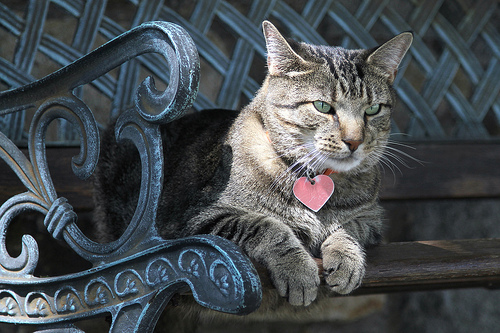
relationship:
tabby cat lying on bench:
[90, 20, 431, 306] [1, 1, 499, 333]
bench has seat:
[1, 1, 499, 333] [1, 140, 499, 296]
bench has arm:
[1, 1, 499, 333] [0, 21, 263, 325]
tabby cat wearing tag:
[90, 20, 431, 306] [292, 173, 336, 212]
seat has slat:
[1, 140, 499, 296] [178, 236, 498, 295]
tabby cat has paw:
[90, 20, 431, 306] [269, 251, 321, 306]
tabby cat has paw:
[90, 20, 431, 306] [320, 234, 366, 294]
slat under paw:
[178, 236, 498, 295] [269, 251, 321, 306]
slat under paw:
[178, 236, 498, 295] [320, 234, 366, 294]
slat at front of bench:
[178, 236, 498, 295] [1, 1, 499, 333]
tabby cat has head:
[90, 20, 431, 306] [261, 21, 413, 172]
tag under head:
[292, 173, 336, 212] [261, 21, 413, 172]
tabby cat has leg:
[90, 20, 431, 306] [155, 156, 321, 307]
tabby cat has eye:
[90, 20, 431, 306] [313, 100, 334, 114]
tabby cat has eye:
[90, 20, 431, 306] [365, 102, 381, 116]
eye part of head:
[313, 100, 334, 114] [261, 21, 413, 172]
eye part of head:
[365, 102, 381, 116] [261, 21, 413, 172]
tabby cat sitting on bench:
[90, 20, 431, 306] [1, 1, 499, 333]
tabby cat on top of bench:
[90, 20, 431, 306] [1, 1, 499, 333]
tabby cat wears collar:
[90, 20, 431, 306] [264, 128, 340, 175]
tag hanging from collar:
[292, 173, 336, 212] [264, 128, 340, 175]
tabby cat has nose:
[90, 20, 431, 306] [340, 115, 366, 152]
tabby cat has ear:
[90, 20, 431, 306] [261, 19, 312, 76]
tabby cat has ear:
[90, 20, 431, 306] [365, 30, 414, 88]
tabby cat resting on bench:
[90, 20, 431, 306] [1, 1, 499, 333]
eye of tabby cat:
[313, 100, 334, 114] [90, 20, 431, 306]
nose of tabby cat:
[340, 115, 366, 152] [90, 20, 431, 306]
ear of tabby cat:
[261, 19, 312, 76] [90, 20, 431, 306]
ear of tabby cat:
[365, 30, 414, 88] [90, 20, 431, 306]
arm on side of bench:
[0, 21, 263, 325] [1, 1, 499, 333]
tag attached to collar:
[292, 173, 336, 212] [264, 128, 340, 175]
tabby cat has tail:
[90, 20, 431, 306] [103, 295, 204, 331]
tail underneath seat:
[103, 295, 204, 331] [1, 140, 499, 296]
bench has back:
[1, 1, 499, 333] [1, 1, 497, 149]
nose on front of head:
[340, 115, 366, 152] [261, 21, 413, 172]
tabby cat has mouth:
[90, 20, 431, 306] [322, 151, 360, 161]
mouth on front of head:
[322, 151, 360, 161] [261, 21, 413, 172]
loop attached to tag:
[305, 166, 318, 183] [292, 173, 336, 212]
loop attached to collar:
[305, 166, 318, 183] [264, 128, 340, 175]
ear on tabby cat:
[365, 30, 414, 88] [90, 17, 432, 333]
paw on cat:
[269, 251, 321, 306] [188, 209, 318, 309]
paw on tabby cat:
[320, 234, 366, 294] [90, 17, 432, 333]